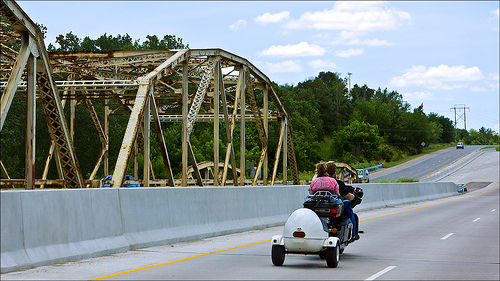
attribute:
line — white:
[364, 208, 497, 281]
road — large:
[0, 184, 498, 279]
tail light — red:
[291, 231, 304, 238]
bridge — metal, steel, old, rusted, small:
[1, 0, 299, 189]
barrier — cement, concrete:
[0, 181, 493, 273]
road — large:
[324, 145, 491, 183]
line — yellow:
[85, 184, 498, 281]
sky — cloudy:
[15, 0, 499, 137]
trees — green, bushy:
[2, 20, 500, 180]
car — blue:
[100, 175, 140, 189]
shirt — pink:
[309, 175, 339, 194]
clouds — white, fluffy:
[229, 2, 480, 105]